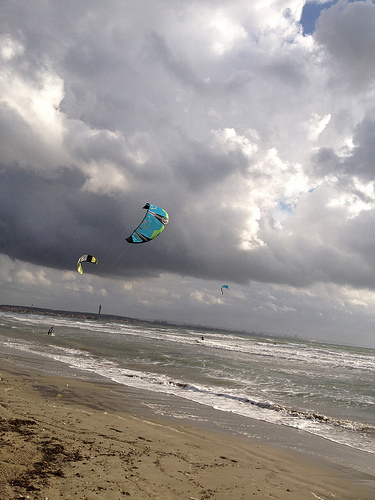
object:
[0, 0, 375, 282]
clouds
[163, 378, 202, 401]
wave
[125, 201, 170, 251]
parachute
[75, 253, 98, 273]
parachute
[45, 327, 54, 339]
person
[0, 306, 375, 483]
water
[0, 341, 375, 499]
sand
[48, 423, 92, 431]
tracks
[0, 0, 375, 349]
sky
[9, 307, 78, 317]
land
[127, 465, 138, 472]
footstep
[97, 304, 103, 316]
light house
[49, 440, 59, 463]
sticks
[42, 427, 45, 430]
cap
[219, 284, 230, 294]
sail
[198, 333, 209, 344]
man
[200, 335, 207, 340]
surfer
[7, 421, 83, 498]
seaweed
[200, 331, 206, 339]
person